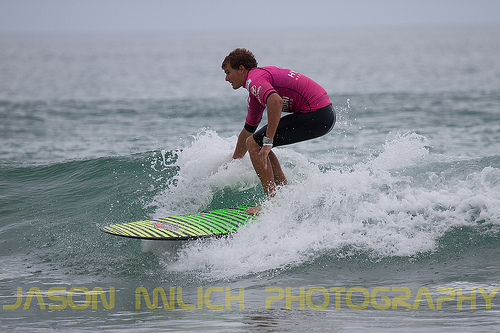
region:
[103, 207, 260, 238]
Green, yellow, and black surf board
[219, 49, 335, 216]
Man surfing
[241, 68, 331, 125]
Maroon swimming shirt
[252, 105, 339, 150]
Black swimming trunks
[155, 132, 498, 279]
Frothy water on the crest of a wave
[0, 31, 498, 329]
A relatively calm ocean during the day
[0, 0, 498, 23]
A blue, cloud-free sky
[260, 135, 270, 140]
Waterproof watch on man's wrist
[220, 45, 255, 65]
Brown, curly hair on man's head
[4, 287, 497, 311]
The photographer's watermark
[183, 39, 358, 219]
A person in the foreground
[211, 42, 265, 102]
A side view of a person's head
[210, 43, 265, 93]
Person has short hair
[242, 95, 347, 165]
Person is wearing shorts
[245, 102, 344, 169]
The shorts are black in color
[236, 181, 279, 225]
Person is not wearing shoes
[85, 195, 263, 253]
The surfboard is striped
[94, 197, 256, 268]
The surfboard is yellow, green and black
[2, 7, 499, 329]
Photo was taken in the daytime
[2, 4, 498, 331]
Photo was taken outdoors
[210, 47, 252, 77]
boy has brown hair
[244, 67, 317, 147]
pink and white shirt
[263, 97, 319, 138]
boy has black shorts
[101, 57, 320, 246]
boy is on surfboard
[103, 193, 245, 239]
green and yellow board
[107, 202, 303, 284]
boy cuts through wave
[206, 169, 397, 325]
white wave around boy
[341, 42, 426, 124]
rippled water behind wave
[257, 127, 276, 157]
boy has grey wristband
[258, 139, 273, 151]
boy has white bracelet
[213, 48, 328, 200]
a man wearing a pink shirt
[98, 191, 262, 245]
a yellow and green surf board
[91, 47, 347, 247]
a man on a surf board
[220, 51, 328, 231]
a man in the water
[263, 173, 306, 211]
splashes around the surf board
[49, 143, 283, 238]
a large wave in the water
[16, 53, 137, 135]
small waves in the water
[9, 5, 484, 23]
the sky above the water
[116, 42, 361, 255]
a surfer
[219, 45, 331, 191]
a man wearing black shorts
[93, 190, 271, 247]
Man on a board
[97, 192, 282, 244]
Man is on a board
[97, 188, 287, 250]
Man on a surfboard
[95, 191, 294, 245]
Man on a yellow, green, and black board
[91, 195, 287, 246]
Man is on a yellow, green, and black board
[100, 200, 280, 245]
Man on a yellow, green, and black surfboard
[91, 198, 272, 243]
Man is on a yellow, green, and black surfboard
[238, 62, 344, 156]
Man wearing a wet suit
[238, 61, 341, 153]
Man is wearing a wet suit